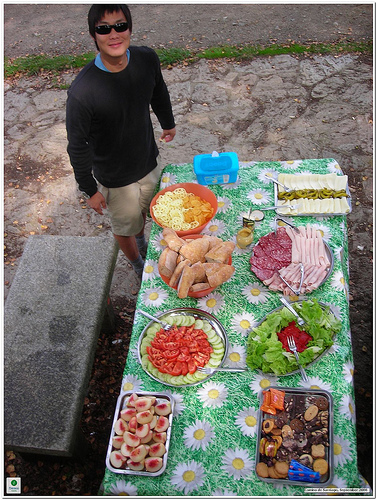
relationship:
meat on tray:
[252, 227, 293, 282] [248, 221, 332, 294]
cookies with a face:
[63, 3, 177, 273] [85, 11, 136, 77]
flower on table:
[256, 164, 280, 186] [99, 158, 360, 496]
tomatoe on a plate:
[147, 323, 214, 376] [139, 306, 226, 385]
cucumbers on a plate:
[140, 312, 225, 383] [139, 306, 226, 385]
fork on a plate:
[199, 364, 246, 379] [137, 302, 231, 388]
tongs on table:
[277, 262, 308, 293] [99, 158, 360, 496]